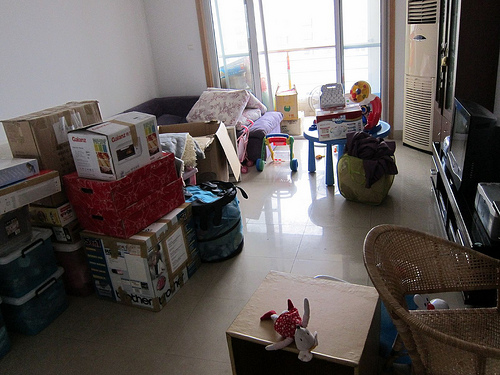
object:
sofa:
[116, 94, 203, 127]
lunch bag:
[321, 83, 347, 111]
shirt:
[272, 308, 309, 340]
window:
[341, 0, 398, 77]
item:
[318, 80, 346, 111]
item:
[350, 80, 370, 103]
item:
[315, 105, 368, 143]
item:
[365, 95, 383, 131]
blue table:
[305, 131, 319, 141]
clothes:
[345, 131, 397, 190]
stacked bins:
[0, 156, 69, 336]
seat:
[455, 314, 485, 336]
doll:
[259, 297, 320, 363]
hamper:
[334, 151, 397, 204]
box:
[77, 200, 202, 312]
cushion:
[184, 85, 252, 124]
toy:
[256, 131, 298, 172]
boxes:
[58, 173, 188, 239]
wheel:
[289, 157, 299, 170]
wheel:
[255, 156, 265, 173]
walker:
[253, 131, 298, 176]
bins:
[0, 118, 212, 313]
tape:
[141, 230, 160, 253]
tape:
[153, 217, 171, 224]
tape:
[174, 202, 189, 208]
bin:
[0, 266, 75, 338]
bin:
[3, 228, 66, 309]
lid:
[10, 268, 66, 309]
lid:
[1, 228, 52, 268]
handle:
[34, 275, 59, 295]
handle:
[19, 236, 44, 258]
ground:
[262, 170, 301, 178]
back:
[360, 220, 498, 375]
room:
[0, 2, 500, 375]